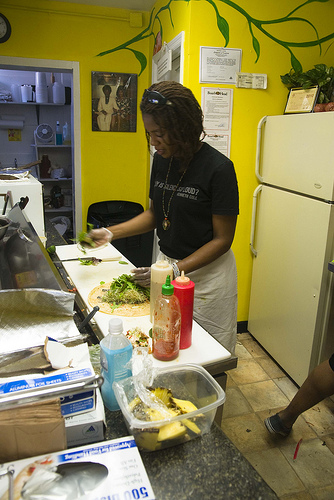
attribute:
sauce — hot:
[130, 278, 232, 375]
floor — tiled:
[232, 375, 294, 497]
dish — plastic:
[163, 358, 211, 437]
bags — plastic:
[18, 456, 140, 499]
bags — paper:
[6, 390, 93, 433]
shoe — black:
[246, 390, 281, 436]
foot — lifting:
[247, 388, 331, 465]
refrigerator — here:
[256, 104, 329, 235]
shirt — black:
[145, 149, 296, 287]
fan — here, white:
[44, 209, 87, 250]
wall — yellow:
[64, 8, 291, 154]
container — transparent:
[134, 365, 210, 422]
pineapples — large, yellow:
[152, 399, 202, 439]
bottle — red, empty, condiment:
[177, 261, 216, 340]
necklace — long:
[148, 185, 188, 224]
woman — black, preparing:
[110, 65, 240, 269]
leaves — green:
[217, 15, 323, 73]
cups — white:
[19, 66, 48, 96]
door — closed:
[247, 127, 328, 308]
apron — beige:
[148, 256, 283, 361]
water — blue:
[99, 316, 153, 414]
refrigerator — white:
[233, 122, 330, 431]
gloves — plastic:
[76, 213, 156, 292]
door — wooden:
[130, 39, 228, 120]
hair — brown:
[153, 87, 221, 156]